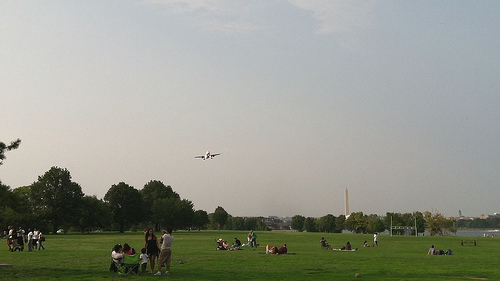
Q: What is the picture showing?
A: People at the park.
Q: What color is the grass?
A: Green.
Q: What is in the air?
A: An airplane.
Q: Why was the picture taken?
A: To capture the people at the park.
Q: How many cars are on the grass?
A: None.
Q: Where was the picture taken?
A: At the park.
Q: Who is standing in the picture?
A: People.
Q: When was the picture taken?
A: During the day.